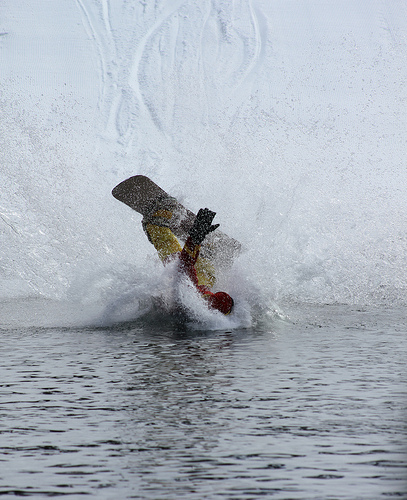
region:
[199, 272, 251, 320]
red hat on man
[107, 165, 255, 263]
dark yellow snow board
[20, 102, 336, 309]
splash caused by man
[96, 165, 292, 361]
man on snow board falling in water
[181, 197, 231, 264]
black snow glove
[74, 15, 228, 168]
board tracks in snow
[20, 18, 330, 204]
snow covered incline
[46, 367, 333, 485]
calm dark blue water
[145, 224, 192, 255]
yellow snow pants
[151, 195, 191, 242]
black and yellow snow boots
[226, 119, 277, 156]
the sand is pure white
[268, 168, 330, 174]
the sand is pure white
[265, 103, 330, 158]
the sand is pure white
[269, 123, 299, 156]
the sand is pure white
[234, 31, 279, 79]
the sand is pure white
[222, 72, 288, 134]
the sand is pure white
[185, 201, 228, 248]
a black glove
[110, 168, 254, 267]
a brown snowboard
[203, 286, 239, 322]
a red hat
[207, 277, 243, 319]
the head of a person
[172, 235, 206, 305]
the arm of a person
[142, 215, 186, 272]
the leg of a person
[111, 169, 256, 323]
a person on a snowboard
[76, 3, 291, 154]
water high in the air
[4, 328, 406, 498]
calm water in front of the person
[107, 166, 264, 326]
a large splash of water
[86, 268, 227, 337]
white water splashing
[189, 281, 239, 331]
man with a red hat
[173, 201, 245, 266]
man with black gloves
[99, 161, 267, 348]
a man falling in the water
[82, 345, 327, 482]
ripples in the water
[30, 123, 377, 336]
water spraying all around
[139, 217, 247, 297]
man wearing yellow pants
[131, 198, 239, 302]
a man with red sleeves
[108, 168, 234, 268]
the man`s feet connected to the board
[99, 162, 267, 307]
the snowboard is black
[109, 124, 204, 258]
the snowboard is black